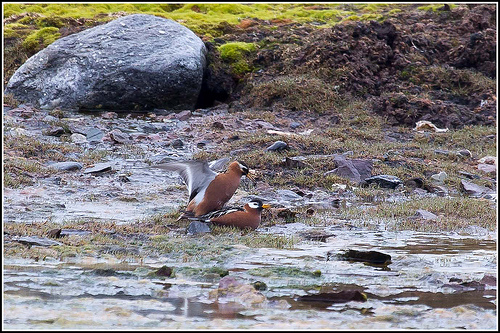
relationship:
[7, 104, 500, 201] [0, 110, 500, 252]
rocks on beach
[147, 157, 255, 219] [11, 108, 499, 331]
bird sitting on ground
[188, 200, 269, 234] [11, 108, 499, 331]
bird sitting on ground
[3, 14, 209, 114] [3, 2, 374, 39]
boulder sitting by grass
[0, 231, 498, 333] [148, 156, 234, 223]
pond by bird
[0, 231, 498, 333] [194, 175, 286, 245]
pond by bird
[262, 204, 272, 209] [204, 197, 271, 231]
beak on bird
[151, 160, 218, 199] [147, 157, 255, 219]
feather on bird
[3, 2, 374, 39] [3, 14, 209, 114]
grass on boulder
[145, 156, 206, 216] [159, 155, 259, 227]
wing on bird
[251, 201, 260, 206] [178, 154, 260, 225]
eye on bird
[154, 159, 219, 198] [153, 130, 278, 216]
wing on bird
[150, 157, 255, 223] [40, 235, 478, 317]
bird on land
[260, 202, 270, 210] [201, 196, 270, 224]
beak on bird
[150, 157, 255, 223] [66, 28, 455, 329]
bird on beach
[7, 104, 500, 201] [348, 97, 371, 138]
rocks in grass